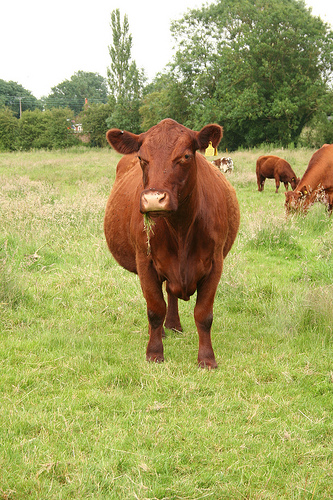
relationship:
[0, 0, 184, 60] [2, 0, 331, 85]
clouds in sky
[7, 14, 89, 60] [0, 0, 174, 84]
clouds in sky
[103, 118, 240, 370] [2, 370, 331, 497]
cattle in field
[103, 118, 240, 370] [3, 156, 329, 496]
cattle in field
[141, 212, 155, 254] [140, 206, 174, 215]
grass in mouth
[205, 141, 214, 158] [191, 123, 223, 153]
tag on ear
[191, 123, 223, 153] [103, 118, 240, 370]
ear on cattle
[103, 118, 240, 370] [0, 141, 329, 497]
cattle in grass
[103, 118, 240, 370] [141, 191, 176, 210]
cattle has nose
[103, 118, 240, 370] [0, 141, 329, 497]
cattle stands in grass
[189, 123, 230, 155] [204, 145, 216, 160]
ear has tag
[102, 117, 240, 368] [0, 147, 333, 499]
cattle grazing in field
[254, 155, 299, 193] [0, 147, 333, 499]
cattle grazing in field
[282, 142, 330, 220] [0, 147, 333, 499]
cattle grazing in field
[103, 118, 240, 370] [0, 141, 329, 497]
cattle standing in grass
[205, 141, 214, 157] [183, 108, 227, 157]
tag on ear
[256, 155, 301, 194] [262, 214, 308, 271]
cattle eating grass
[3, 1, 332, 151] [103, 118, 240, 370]
trees behind a cattle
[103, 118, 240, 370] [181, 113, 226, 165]
cattle has ear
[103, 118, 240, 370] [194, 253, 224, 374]
cattle has front leg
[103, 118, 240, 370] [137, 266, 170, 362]
cattle has front leg